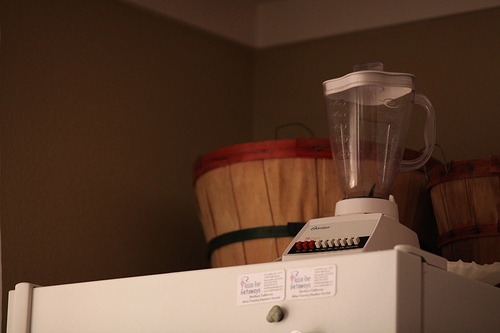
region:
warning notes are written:
[252, 282, 264, 295]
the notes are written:
[299, 286, 313, 301]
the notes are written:
[301, 271, 313, 301]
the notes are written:
[289, 288, 304, 309]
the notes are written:
[319, 285, 327, 307]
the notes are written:
[308, 272, 322, 298]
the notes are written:
[288, 283, 300, 301]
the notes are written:
[307, 280, 317, 300]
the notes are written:
[252, 269, 305, 297]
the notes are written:
[262, 277, 336, 299]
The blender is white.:
[302, 67, 444, 272]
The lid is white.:
[308, 44, 425, 124]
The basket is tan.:
[175, 131, 444, 258]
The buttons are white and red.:
[253, 192, 380, 280]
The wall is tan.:
[46, 53, 163, 225]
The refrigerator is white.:
[5, 271, 340, 331]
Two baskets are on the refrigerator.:
[170, 109, 498, 274]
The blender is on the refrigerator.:
[285, 62, 440, 279]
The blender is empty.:
[258, 51, 435, 296]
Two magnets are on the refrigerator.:
[215, 263, 343, 329]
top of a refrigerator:
[17, 260, 492, 329]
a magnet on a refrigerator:
[254, 300, 301, 325]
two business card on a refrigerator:
[231, 267, 344, 304]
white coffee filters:
[447, 237, 498, 292]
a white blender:
[291, 67, 439, 257]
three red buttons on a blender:
[289, 230, 316, 254]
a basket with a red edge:
[172, 127, 337, 251]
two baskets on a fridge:
[200, 127, 497, 219]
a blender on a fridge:
[277, 57, 432, 257]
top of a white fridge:
[18, 262, 493, 331]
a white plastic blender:
[277, 58, 447, 263]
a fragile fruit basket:
[169, 139, 359, 263]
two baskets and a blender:
[200, 42, 492, 262]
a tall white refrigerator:
[5, 236, 498, 332]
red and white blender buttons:
[290, 236, 363, 248]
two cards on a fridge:
[232, 259, 344, 301]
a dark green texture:
[48, 68, 160, 240]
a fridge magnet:
[256, 302, 292, 324]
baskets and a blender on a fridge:
[187, 51, 498, 318]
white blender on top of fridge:
[281, 53, 429, 286]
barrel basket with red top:
[179, 83, 349, 268]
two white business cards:
[234, 263, 352, 311]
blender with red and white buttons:
[248, 61, 428, 300]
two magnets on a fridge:
[231, 265, 353, 305]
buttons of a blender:
[291, 228, 371, 253]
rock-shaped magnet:
[258, 301, 293, 326]